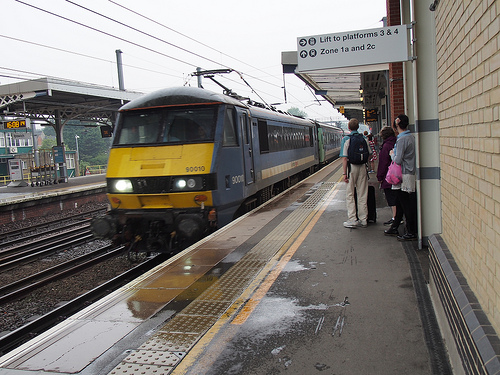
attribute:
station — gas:
[0, 120, 91, 187]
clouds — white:
[6, 1, 278, 60]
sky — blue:
[1, 0, 388, 91]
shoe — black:
[394, 222, 426, 243]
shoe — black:
[380, 224, 401, 236]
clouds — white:
[199, 0, 290, 41]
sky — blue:
[2, 4, 294, 49]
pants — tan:
[343, 163, 374, 228]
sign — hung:
[292, 23, 409, 71]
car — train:
[90, 87, 367, 242]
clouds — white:
[206, 12, 261, 40]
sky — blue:
[210, 22, 291, 67]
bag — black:
[350, 132, 367, 161]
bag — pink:
[386, 159, 403, 184]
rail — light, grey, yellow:
[103, 77, 289, 250]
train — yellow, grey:
[91, 78, 349, 267]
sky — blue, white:
[202, 15, 321, 62]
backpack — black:
[345, 133, 374, 172]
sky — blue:
[2, 0, 391, 122]